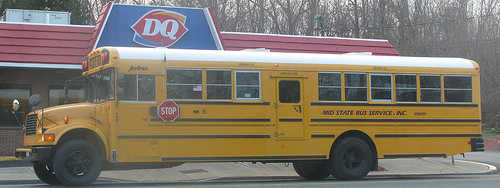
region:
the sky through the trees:
[258, 5, 293, 19]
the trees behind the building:
[222, 1, 439, 18]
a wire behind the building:
[319, 15, 498, 30]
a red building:
[11, 18, 427, 83]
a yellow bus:
[17, 40, 485, 178]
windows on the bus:
[166, 68, 255, 100]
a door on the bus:
[276, 80, 304, 132]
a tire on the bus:
[51, 140, 103, 178]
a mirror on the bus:
[10, 98, 18, 108]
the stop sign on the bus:
[153, 100, 186, 118]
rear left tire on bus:
[331, 135, 381, 178]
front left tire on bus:
[55, 136, 106, 182]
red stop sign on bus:
[152, 100, 186, 120]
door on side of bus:
[272, 80, 308, 140]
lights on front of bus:
[36, 130, 60, 142]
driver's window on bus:
[122, 72, 160, 98]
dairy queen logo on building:
[130, 4, 196, 52]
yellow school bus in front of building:
[11, 45, 495, 184]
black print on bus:
[318, 104, 434, 120]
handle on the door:
[294, 104, 305, 115]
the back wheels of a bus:
[292, 138, 372, 178]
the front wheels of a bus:
[29, 140, 103, 178]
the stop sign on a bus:
[154, 100, 181, 122]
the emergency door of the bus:
[267, 74, 312, 140]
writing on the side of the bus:
[317, 103, 437, 126]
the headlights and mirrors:
[10, 95, 62, 141]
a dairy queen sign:
[131, 7, 191, 54]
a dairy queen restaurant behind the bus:
[0, 5, 409, 160]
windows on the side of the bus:
[166, 62, 475, 114]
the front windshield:
[82, 67, 114, 102]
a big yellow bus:
[3, 11, 499, 181]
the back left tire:
[306, 120, 384, 185]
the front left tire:
[41, 130, 106, 186]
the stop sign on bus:
[153, 90, 185, 127]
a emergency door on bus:
[261, 68, 308, 157]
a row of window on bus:
[111, 65, 484, 111]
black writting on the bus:
[302, 100, 414, 125]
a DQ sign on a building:
[65, 0, 241, 56]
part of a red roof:
[0, 8, 92, 77]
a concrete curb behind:
[453, 142, 496, 186]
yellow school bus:
[6, 30, 498, 187]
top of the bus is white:
[105, 38, 480, 76]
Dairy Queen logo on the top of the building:
[122, 5, 200, 45]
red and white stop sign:
[156, 93, 184, 128]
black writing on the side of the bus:
[316, 103, 413, 120]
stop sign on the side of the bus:
[153, 95, 188, 126]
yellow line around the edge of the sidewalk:
[443, 148, 499, 177]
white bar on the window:
[165, 80, 205, 90]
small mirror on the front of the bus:
[8, 95, 23, 113]